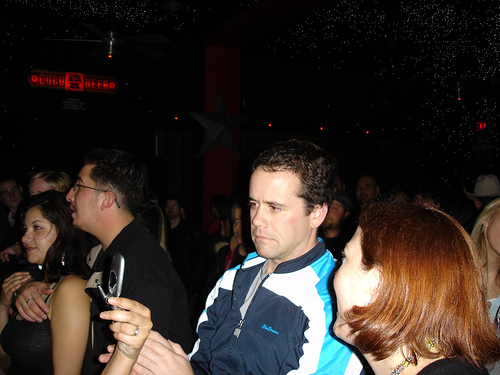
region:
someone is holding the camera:
[100, 280, 142, 342]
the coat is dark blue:
[260, 318, 280, 346]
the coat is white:
[280, 281, 307, 297]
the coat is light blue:
[321, 263, 332, 279]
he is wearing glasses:
[67, 173, 92, 194]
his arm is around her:
[8, 274, 75, 317]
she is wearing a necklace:
[393, 355, 423, 369]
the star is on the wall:
[190, 93, 241, 153]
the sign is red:
[38, 72, 77, 93]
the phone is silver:
[105, 255, 131, 292]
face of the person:
[227, 145, 306, 257]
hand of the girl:
[96, 300, 165, 357]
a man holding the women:
[6, 143, 172, 353]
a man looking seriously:
[231, 158, 360, 280]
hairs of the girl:
[356, 291, 468, 373]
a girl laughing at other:
[323, 208, 488, 366]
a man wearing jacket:
[193, 152, 348, 371]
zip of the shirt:
[213, 265, 284, 350]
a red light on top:
[26, 47, 151, 130]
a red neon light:
[28, 69, 115, 96]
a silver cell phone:
[97, 252, 125, 308]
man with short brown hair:
[250, 138, 332, 258]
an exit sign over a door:
[473, 120, 488, 131]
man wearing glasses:
[67, 177, 126, 209]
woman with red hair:
[333, 202, 498, 367]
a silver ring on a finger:
[129, 324, 143, 339]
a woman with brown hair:
[14, 188, 91, 283]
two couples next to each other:
[0, 146, 496, 372]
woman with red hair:
[332, 200, 497, 373]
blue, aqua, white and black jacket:
[185, 235, 372, 370]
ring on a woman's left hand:
[131, 323, 139, 335]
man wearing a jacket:
[185, 146, 370, 372]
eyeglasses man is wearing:
[65, 177, 110, 194]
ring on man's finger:
[22, 295, 33, 305]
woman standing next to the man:
[0, 190, 90, 372]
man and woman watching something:
[127, 147, 490, 372]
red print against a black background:
[28, 70, 118, 96]